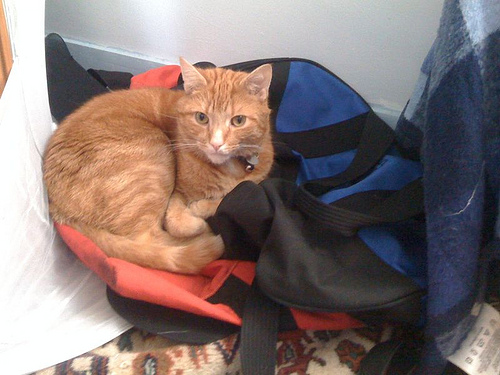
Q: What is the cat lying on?
A: Duffle bag.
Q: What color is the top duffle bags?
A: Blue.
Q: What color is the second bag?
A: Red.